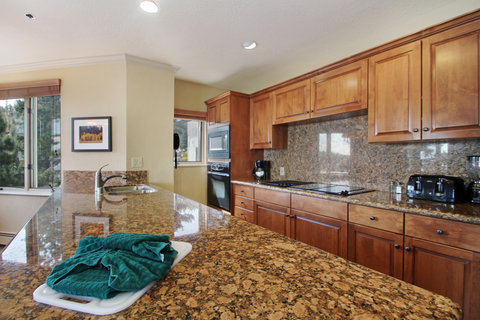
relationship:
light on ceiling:
[135, 1, 163, 14] [277, 13, 354, 48]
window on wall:
[0, 84, 60, 192] [62, 67, 125, 169]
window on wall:
[174, 119, 204, 162] [129, 60, 172, 170]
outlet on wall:
[128, 153, 149, 168] [61, 61, 176, 171]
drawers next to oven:
[229, 180, 255, 221] [203, 164, 231, 211]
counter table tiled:
[0, 184, 444, 317] [177, 292, 350, 320]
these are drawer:
[237, 199, 478, 220] [402, 212, 478, 249]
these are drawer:
[237, 199, 478, 220] [233, 180, 254, 197]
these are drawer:
[237, 199, 478, 220] [232, 195, 256, 209]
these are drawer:
[237, 199, 478, 220] [232, 206, 257, 220]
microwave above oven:
[197, 120, 236, 163] [195, 158, 242, 213]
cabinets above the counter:
[204, 6, 479, 148] [231, 174, 479, 224]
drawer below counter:
[349, 203, 405, 235] [349, 179, 479, 235]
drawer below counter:
[404, 214, 478, 250] [349, 179, 479, 235]